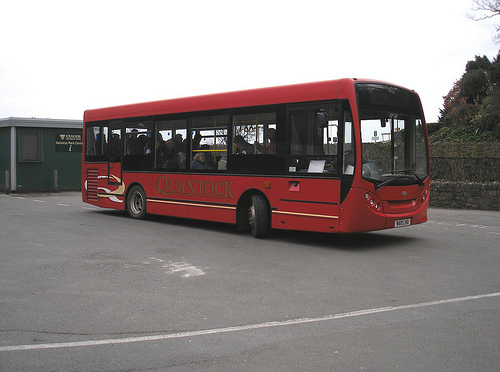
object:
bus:
[82, 79, 429, 236]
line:
[1, 291, 499, 354]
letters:
[157, 175, 235, 199]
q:
[156, 175, 169, 196]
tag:
[393, 219, 412, 229]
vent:
[86, 168, 100, 201]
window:
[187, 114, 229, 174]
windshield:
[355, 83, 430, 185]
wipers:
[375, 171, 423, 190]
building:
[0, 117, 84, 194]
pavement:
[0, 191, 499, 372]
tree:
[436, 53, 499, 135]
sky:
[3, 0, 500, 125]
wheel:
[124, 183, 148, 217]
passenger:
[189, 150, 214, 171]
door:
[107, 121, 123, 185]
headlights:
[363, 192, 379, 209]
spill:
[148, 253, 207, 280]